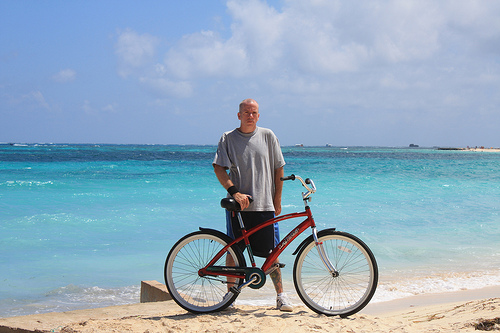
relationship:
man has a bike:
[213, 96, 294, 314] [164, 174, 379, 318]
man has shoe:
[213, 96, 294, 314] [276, 296, 297, 313]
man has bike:
[213, 96, 294, 314] [164, 174, 379, 318]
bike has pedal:
[164, 174, 379, 318] [228, 286, 241, 297]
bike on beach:
[164, 174, 379, 318] [0, 284, 497, 330]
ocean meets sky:
[1, 142, 497, 314] [1, 1, 498, 149]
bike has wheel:
[164, 174, 379, 318] [292, 230, 379, 319]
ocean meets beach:
[1, 142, 497, 314] [0, 284, 497, 330]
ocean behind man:
[1, 142, 497, 314] [213, 96, 294, 314]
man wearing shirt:
[213, 96, 294, 314] [213, 127, 286, 214]